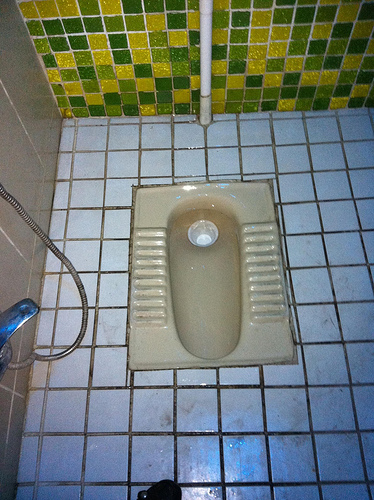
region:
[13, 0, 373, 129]
Green and yellow tile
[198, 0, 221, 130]
Skinny white pvc pole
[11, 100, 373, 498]
Small white square tiles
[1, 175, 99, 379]
Small skinny silver pipe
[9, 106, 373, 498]
Black grout between white tiles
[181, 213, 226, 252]
Small white circle drain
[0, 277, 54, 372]
Small silver faucet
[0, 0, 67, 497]
Large brown shiny tiles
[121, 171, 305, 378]
Square brown water hole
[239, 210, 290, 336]
White food pads on water hole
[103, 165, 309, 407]
Urinal on the floor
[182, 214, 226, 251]
Drain to catch pee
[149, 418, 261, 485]
The floor is very dirty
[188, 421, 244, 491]
Reflection on the floor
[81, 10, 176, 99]
Wall is green tile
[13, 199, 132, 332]
Pipe hooked to the water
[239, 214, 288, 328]
Place to put feet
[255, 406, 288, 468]
Grout in between the tiles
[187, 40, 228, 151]
Pipe on the wall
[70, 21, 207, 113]
The tiles are mismatched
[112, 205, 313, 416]
this is a drain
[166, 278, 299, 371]
the drain is large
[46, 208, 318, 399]
the bathroom is dirty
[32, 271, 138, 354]
this is a metal coil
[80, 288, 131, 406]
this is a rusty coil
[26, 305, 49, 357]
this is a handle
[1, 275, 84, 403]
the handle is metal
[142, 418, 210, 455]
these are some cracks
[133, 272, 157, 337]
this is quite ridged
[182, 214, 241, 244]
this is a tint cup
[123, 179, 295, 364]
ridged gray urinal with oval center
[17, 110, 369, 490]
wet and grimy square floor tiles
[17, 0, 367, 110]
white pipe against wall of glittery green and yellow tiles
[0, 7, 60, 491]
plain gray tiles on side wall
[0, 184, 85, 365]
curved and kinked metal cord leading to metal lever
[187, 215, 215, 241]
white drain with white liquid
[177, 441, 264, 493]
reflection of light on some floor tiles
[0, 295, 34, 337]
prints and film on lever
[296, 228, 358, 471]
footprints along side of urinal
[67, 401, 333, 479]
dark grout between tiles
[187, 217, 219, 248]
a white plastic drain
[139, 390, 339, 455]
dirty white tile on the floor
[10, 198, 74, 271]
a metal nozzle hose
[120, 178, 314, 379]
a beige toilet in the floor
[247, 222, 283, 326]
grooves in the side of the toilet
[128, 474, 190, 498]
a black object on the floor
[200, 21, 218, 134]
a white pvc pipe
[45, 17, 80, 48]
dark green wall tiles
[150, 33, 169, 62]
light green wall tiles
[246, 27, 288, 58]
yellow wall tiles